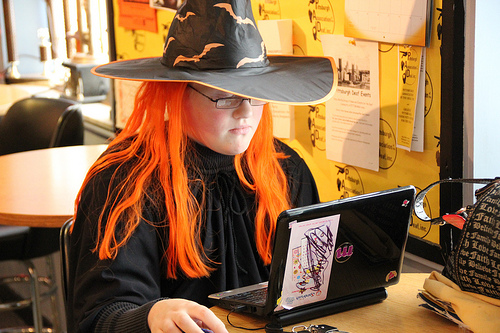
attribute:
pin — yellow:
[348, 30, 360, 48]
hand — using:
[165, 299, 215, 331]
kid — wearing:
[71, 0, 343, 331]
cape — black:
[85, 164, 295, 224]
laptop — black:
[180, 178, 434, 327]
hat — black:
[77, 0, 354, 116]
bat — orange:
[166, 35, 231, 74]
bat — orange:
[231, 34, 275, 75]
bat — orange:
[215, 0, 261, 36]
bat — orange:
[169, 5, 201, 27]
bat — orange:
[157, 27, 177, 57]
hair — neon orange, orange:
[58, 57, 313, 282]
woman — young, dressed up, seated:
[60, 1, 359, 333]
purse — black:
[410, 159, 500, 309]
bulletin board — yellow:
[96, 1, 467, 265]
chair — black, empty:
[0, 85, 91, 153]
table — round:
[0, 133, 128, 226]